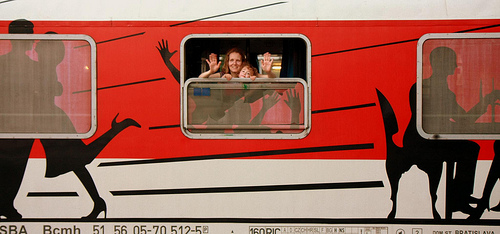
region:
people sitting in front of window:
[123, 23, 351, 180]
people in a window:
[126, 11, 351, 163]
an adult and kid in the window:
[158, 12, 407, 166]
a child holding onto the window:
[139, 11, 337, 157]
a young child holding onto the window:
[157, 26, 292, 148]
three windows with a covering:
[10, 8, 497, 173]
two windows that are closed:
[29, 8, 499, 200]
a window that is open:
[74, 12, 485, 232]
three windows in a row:
[10, 6, 497, 207]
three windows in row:
[34, 1, 497, 200]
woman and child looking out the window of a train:
[198, 44, 285, 89]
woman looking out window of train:
[218, 49, 244, 76]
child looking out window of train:
[239, 64, 252, 76]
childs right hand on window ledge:
[248, 72, 255, 80]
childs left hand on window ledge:
[218, 70, 233, 80]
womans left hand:
[203, 49, 223, 71]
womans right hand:
[255, 49, 274, 73]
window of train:
[175, 30, 311, 140]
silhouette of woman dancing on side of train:
[30, 27, 141, 219]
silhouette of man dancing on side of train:
[0, 19, 42, 219]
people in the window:
[185, 35, 280, 130]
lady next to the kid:
[213, 48, 248, 85]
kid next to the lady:
[236, 60, 261, 88]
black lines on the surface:
[319, 88, 363, 168]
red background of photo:
[314, 57, 369, 94]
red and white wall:
[318, 86, 373, 195]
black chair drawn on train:
[357, 83, 412, 194]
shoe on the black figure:
[111, 98, 146, 142]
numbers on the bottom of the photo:
[143, 225, 201, 232]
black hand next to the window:
[148, 30, 175, 72]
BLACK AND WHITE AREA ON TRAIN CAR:
[104, 175, 384, 222]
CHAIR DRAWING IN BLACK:
[363, 84, 420, 216]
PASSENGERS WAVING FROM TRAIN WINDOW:
[163, 30, 318, 143]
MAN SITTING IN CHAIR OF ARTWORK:
[368, 26, 481, 219]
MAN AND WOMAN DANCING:
[1, 14, 135, 220]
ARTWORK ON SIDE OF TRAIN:
[95, 1, 184, 220]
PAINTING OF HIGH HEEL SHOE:
[105, 105, 140, 135]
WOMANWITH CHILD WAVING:
[200, 50, 285, 79]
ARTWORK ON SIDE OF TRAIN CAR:
[0, 4, 499, 232]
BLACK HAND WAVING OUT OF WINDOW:
[150, 35, 180, 84]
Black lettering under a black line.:
[0, 220, 497, 232]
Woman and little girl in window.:
[196, 49, 291, 81]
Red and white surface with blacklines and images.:
[0, 0, 499, 221]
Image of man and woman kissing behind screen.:
[0, 16, 143, 217]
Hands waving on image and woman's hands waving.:
[157, 36, 314, 134]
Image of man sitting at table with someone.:
[376, 45, 497, 220]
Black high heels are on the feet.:
[81, 110, 141, 218]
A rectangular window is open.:
[178, 35, 310, 135]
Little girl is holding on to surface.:
[222, 62, 257, 78]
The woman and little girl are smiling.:
[225, 50, 256, 76]